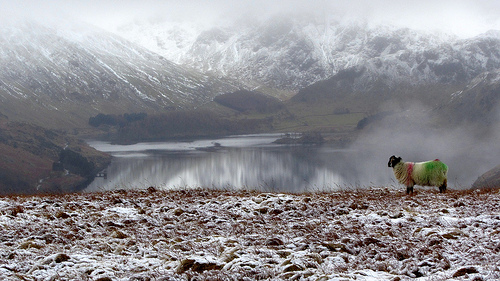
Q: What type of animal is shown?
A: Sheep.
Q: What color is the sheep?
A: Black, white, pink, green.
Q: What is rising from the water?
A: Mist.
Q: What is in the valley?
A: Lake.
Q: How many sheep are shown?
A: One.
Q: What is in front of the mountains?
A: Lake.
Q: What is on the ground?
A: Snow.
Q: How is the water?
A: Calm.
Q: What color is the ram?
A: Green white and red.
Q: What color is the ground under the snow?
A: Brown.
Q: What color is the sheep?
A: Red and green.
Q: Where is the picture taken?
A: In the mountains.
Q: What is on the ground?
A: Snow.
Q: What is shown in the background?
A: Mountains.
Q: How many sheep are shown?
A: One.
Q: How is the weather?
A: Misty.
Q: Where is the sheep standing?
A: A field.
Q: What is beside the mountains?
A: A lake.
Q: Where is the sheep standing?
A: Beside water.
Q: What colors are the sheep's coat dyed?
A: Red and green.